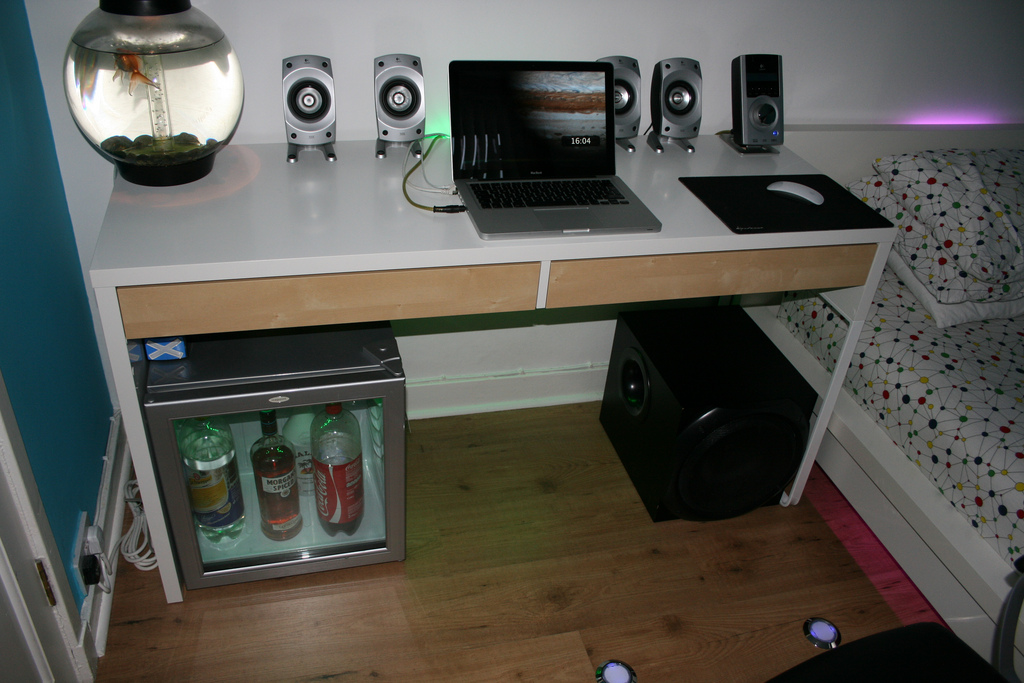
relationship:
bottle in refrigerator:
[176, 419, 245, 544] [143, 325, 409, 593]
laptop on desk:
[449, 60, 661, 241] [80, 153, 884, 558]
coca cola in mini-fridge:
[310, 402, 362, 539] [181, 422, 248, 537]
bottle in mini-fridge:
[247, 410, 304, 541] [181, 422, 248, 537]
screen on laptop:
[441, 65, 619, 184] [449, 60, 661, 241]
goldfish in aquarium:
[112, 48, 159, 96] [65, 0, 246, 188]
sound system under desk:
[595, 303, 816, 524] [251, 206, 452, 321]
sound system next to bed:
[595, 303, 816, 524] [784, 135, 1007, 660]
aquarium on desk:
[65, 0, 246, 188] [177, 199, 217, 236]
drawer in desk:
[303, 299, 321, 310] [132, 206, 463, 258]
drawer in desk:
[627, 269, 649, 287] [132, 206, 463, 258]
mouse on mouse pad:
[773, 180, 832, 209] [677, 173, 893, 235]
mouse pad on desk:
[677, 173, 893, 235] [184, 188, 396, 251]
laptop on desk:
[449, 60, 661, 241] [181, 202, 382, 246]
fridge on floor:
[135, 320, 408, 591] [460, 552, 482, 589]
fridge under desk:
[135, 320, 408, 591] [132, 191, 392, 254]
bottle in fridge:
[285, 418, 307, 436] [136, 333, 422, 593]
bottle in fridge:
[259, 411, 299, 537] [136, 333, 422, 593]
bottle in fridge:
[177, 418, 247, 540] [136, 333, 422, 593]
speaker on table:
[277, 50, 336, 165] [162, 210, 337, 258]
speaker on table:
[378, 50, 422, 157] [296, 210, 307, 221]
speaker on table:
[605, 57, 638, 146] [266, 210, 303, 243]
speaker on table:
[657, 61, 709, 150] [225, 173, 247, 187]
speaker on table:
[728, 53, 787, 157] [244, 202, 255, 205]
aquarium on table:
[65, 0, 246, 188] [300, 214, 307, 225]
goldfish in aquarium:
[95, 46, 158, 90] [65, 0, 246, 188]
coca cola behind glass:
[311, 407, 363, 533] [303, 530, 306, 533]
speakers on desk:
[280, 46, 469, 198] [217, 165, 419, 259]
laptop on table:
[449, 60, 661, 241] [185, 214, 358, 271]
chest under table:
[234, 392, 355, 567] [150, 223, 356, 276]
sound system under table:
[595, 331, 779, 524] [236, 161, 388, 278]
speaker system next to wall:
[217, 18, 840, 166] [336, 10, 449, 62]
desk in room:
[90, 131, 901, 577] [66, 64, 699, 536]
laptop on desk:
[461, 74, 608, 250] [90, 131, 901, 577]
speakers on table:
[282, 54, 425, 165] [247, 167, 362, 274]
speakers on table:
[608, 59, 786, 148] [263, 191, 370, 261]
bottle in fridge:
[247, 410, 304, 541] [135, 320, 408, 591]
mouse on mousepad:
[767, 181, 824, 206] [697, 163, 784, 263]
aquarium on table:
[65, 0, 246, 188] [247, 197, 414, 267]